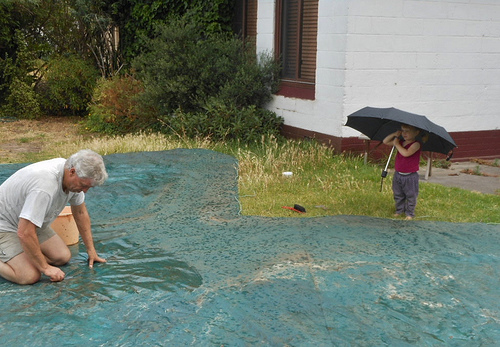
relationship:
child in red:
[382, 123, 421, 221] [392, 152, 402, 167]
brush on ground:
[277, 197, 312, 217] [263, 200, 298, 218]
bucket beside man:
[46, 202, 82, 248] [0, 147, 107, 284]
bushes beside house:
[88, 91, 163, 116] [220, 2, 497, 158]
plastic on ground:
[2, 147, 497, 346] [2, 98, 498, 345]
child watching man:
[381, 123, 422, 218] [0, 147, 107, 284]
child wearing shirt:
[382, 123, 421, 221] [391, 139, 422, 172]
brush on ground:
[131, 4, 287, 147] [273, 229, 425, 302]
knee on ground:
[14, 265, 41, 287] [2, 98, 498, 345]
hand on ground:
[80, 250, 112, 269] [178, 217, 254, 244]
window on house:
[268, 1, 319, 101] [220, 2, 497, 158]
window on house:
[227, 1, 262, 59] [220, 2, 497, 158]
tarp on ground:
[2, 135, 497, 345] [2, 98, 498, 345]